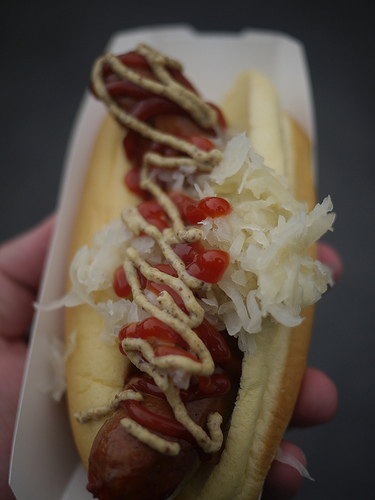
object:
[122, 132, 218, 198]
ketchup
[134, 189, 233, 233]
ketchup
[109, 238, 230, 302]
ketchup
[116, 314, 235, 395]
ketchup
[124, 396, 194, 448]
ketchup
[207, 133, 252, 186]
sauerkraut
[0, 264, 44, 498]
palm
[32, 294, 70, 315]
sauerkraut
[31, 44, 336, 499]
hot dog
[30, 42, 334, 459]
toppings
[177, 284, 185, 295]
condiments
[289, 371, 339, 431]
finger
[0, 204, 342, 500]
hand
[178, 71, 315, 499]
bun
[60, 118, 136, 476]
bun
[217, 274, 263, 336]
saurkraut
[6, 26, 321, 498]
box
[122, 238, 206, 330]
mustard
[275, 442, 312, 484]
sauerkraut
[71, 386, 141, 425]
mustard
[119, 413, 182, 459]
line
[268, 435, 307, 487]
finger